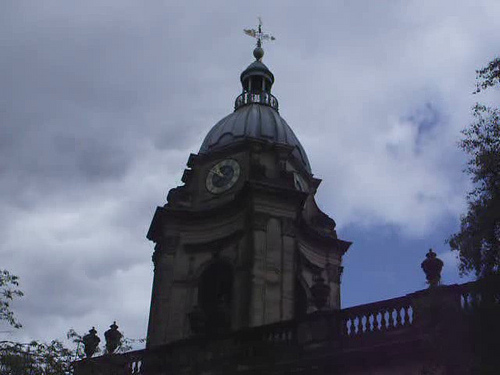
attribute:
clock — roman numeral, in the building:
[197, 156, 242, 196]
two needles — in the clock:
[209, 163, 223, 182]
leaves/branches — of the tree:
[0, 264, 61, 372]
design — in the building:
[185, 257, 248, 332]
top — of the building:
[195, 3, 312, 165]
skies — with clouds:
[2, 3, 180, 159]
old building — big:
[134, 11, 364, 365]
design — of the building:
[294, 247, 334, 315]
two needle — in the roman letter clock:
[208, 160, 226, 180]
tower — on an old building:
[141, 8, 352, 346]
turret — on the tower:
[241, 16, 276, 47]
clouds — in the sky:
[319, 35, 449, 195]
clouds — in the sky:
[11, 21, 151, 247]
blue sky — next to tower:
[6, 7, 207, 130]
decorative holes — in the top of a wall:
[206, 285, 444, 372]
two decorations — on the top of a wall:
[76, 320, 127, 357]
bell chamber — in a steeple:
[189, 251, 232, 336]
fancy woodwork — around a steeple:
[146, 178, 350, 246]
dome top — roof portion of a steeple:
[196, 102, 316, 168]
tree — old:
[0, 263, 95, 373]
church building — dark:
[120, 15, 350, 371]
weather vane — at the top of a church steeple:
[238, 14, 278, 64]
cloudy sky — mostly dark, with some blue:
[2, 5, 443, 208]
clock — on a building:
[203, 155, 242, 195]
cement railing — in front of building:
[74, 280, 464, 369]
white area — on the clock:
[205, 160, 239, 190]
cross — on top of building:
[243, 17, 275, 54]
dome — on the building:
[199, 106, 313, 176]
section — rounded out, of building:
[151, 205, 252, 345]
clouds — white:
[6, 10, 486, 230]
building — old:
[128, 12, 373, 344]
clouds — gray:
[24, 26, 154, 178]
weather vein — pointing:
[239, 12, 279, 50]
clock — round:
[197, 155, 244, 198]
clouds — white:
[348, 54, 400, 141]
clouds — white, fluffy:
[30, 95, 130, 316]